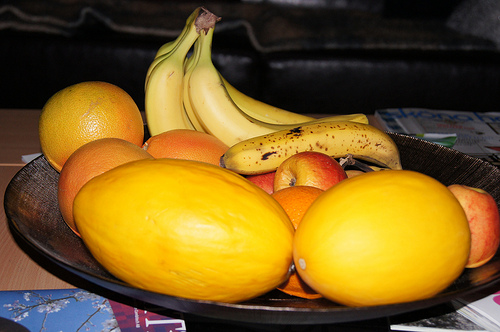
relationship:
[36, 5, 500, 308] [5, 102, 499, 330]
fruit on a plate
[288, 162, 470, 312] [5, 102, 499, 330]
fruit on a plate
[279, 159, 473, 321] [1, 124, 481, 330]
melon on a plate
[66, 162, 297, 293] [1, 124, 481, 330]
melon on a plate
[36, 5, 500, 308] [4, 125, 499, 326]
fruit inside bowl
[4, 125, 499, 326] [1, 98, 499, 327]
bowl on top of table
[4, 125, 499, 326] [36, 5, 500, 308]
bowl holding fruit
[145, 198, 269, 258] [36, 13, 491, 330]
light hitting fruit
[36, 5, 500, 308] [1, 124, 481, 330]
fruit on plate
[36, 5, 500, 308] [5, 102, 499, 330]
fruit arranged on plate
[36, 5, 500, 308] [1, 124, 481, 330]
fruit stacked up on plate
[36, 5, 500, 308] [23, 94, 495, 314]
fruit on plate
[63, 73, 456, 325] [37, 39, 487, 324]
fruit on bowl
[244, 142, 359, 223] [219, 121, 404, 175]
apple next to banana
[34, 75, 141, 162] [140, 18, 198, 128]
orange next to banana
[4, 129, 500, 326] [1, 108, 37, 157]
bowl on table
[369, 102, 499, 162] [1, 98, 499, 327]
magazine on table